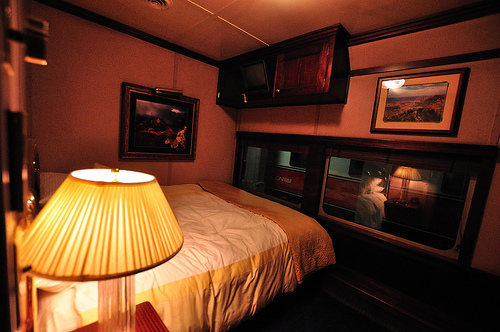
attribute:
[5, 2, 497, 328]
bedroom — dark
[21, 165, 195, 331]
lamp — on, illuminated, tan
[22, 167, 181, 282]
shade — pleated, yellow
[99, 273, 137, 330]
pedestal — glass, clear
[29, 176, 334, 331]
comforter — white, yellow, quilted, patchwork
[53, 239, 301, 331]
hem — yellow, wide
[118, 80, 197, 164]
picture — dark, matted, framed, large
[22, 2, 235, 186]
wall — wooden, light pink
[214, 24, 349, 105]
cabinet — dark, wooden, hanging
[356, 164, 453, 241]
reflection — lamp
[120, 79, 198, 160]
frame — dark wood, rectangle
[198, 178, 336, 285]
blanket — folded, orange, yellow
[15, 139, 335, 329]
bed — made, queen size, large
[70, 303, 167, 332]
side table — dark brown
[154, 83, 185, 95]
wall lamp — small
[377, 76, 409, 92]
reflection — of lamp, lamp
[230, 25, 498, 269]
wall — light pink